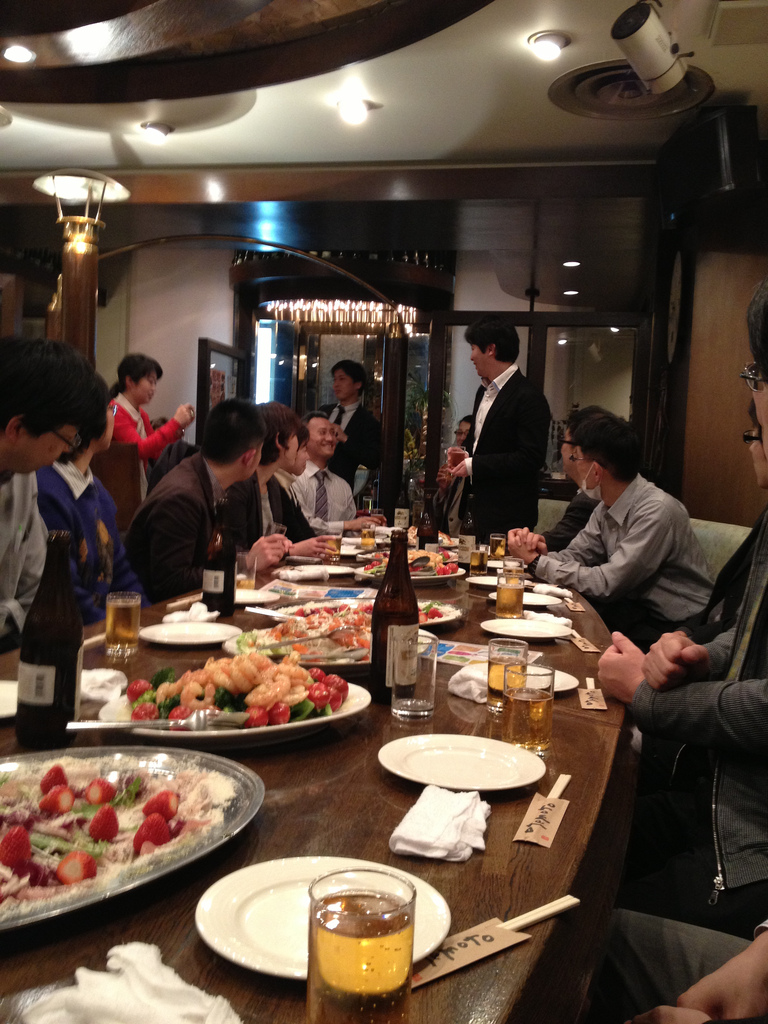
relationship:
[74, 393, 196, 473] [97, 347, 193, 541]
sweater on woman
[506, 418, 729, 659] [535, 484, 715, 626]
man wearing shirt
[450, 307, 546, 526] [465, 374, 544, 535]
man wearing jacket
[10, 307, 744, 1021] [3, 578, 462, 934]
people enjoying meals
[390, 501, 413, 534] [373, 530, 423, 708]
glass of wine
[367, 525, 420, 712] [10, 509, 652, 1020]
bottle on table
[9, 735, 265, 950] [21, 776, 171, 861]
tray of strawberry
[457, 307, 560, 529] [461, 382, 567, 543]
man with suit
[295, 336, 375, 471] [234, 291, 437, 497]
man at door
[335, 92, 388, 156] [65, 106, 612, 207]
lights on ceiling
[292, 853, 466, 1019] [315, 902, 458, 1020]
glass with liquid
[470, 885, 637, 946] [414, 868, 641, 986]
chopsticks in paper holder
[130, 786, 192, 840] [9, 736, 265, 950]
radishes in tray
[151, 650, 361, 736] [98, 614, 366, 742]
shrimp in tray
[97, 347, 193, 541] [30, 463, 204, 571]
woman has shirt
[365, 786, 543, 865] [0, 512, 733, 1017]
towel on table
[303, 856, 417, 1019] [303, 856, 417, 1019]
glass with glass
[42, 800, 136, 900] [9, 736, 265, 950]
radishes on tray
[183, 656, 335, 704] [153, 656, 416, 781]
shrimp on tray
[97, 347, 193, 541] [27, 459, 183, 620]
woman has shirt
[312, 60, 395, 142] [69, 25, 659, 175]
lights on ceiling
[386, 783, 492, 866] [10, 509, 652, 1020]
napkins on table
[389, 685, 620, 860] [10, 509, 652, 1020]
plate on table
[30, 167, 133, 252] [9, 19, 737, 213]
light hanging from ceiling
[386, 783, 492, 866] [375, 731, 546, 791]
napkins laying by plate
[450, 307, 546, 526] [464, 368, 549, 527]
man wearing a suit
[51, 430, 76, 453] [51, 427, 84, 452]
side of a eyeglasses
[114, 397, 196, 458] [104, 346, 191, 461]
arm of a woman